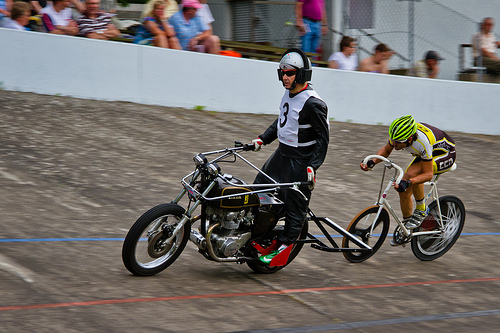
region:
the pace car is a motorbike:
[81, 50, 476, 282]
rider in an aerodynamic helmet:
[339, 110, 481, 269]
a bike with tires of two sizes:
[332, 176, 482, 286]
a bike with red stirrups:
[92, 45, 339, 290]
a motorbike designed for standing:
[108, 50, 339, 297]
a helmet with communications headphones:
[265, 49, 321, 98]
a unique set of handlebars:
[170, 126, 320, 216]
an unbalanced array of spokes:
[405, 189, 476, 265]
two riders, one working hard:
[185, 51, 477, 278]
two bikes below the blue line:
[2, 207, 498, 278]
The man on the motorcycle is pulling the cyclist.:
[110, 17, 475, 297]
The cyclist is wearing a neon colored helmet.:
[385, 110, 412, 150]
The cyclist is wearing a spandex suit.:
[380, 110, 466, 250]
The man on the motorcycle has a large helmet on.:
[270, 45, 310, 100]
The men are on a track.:
[5, 90, 490, 320]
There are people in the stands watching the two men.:
[2, 0, 487, 80]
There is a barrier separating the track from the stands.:
[0, 25, 495, 135]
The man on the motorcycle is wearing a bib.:
[266, 85, 327, 145]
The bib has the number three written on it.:
[275, 95, 300, 140]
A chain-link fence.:
[355, 1, 461, 49]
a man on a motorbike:
[117, 52, 338, 277]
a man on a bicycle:
[342, 105, 469, 265]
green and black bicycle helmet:
[383, 110, 421, 150]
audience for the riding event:
[142, 0, 243, 58]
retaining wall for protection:
[85, 51, 255, 117]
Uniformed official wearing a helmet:
[236, 50, 336, 245]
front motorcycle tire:
[115, 198, 195, 278]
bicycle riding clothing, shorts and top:
[387, 111, 460, 177]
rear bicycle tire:
[406, 187, 469, 264]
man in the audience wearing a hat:
[407, 45, 448, 86]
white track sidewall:
[4, 25, 481, 132]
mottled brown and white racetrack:
[23, 97, 473, 329]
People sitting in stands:
[52, 6, 494, 78]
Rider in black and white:
[247, 39, 329, 252]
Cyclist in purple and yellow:
[369, 107, 466, 280]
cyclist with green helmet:
[336, 109, 486, 279]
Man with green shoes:
[237, 45, 319, 271]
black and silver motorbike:
[105, 135, 373, 281]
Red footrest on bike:
[247, 230, 297, 269]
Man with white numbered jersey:
[228, 43, 333, 244]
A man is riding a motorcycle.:
[111, 40, 336, 281]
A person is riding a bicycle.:
[335, 105, 467, 267]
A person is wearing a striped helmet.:
[380, 110, 417, 150]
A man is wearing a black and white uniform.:
[225, 45, 332, 245]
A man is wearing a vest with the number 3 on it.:
[265, 80, 332, 150]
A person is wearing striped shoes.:
[400, 196, 430, 236]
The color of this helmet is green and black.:
[385, 110, 420, 148]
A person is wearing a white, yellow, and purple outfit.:
[381, 111, 461, 184]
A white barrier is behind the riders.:
[0, 20, 499, 136]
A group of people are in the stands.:
[0, 0, 499, 85]